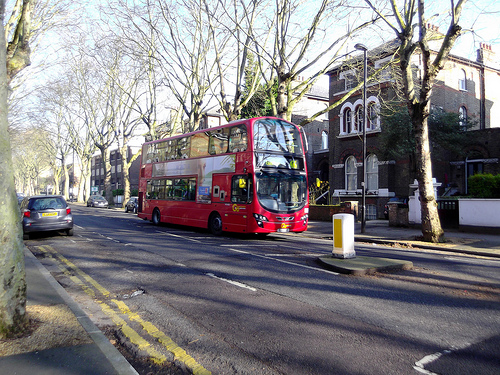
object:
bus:
[136, 115, 310, 236]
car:
[21, 194, 75, 239]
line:
[43, 244, 213, 374]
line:
[205, 270, 259, 293]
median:
[330, 212, 357, 260]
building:
[323, 19, 499, 220]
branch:
[450, 0, 456, 28]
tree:
[362, 0, 477, 244]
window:
[338, 101, 353, 137]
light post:
[353, 42, 367, 236]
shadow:
[410, 63, 495, 129]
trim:
[331, 158, 395, 170]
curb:
[355, 235, 500, 259]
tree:
[196, 0, 398, 128]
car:
[123, 195, 138, 214]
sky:
[1, 0, 500, 179]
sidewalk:
[353, 219, 499, 258]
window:
[251, 118, 304, 156]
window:
[254, 166, 308, 212]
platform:
[316, 251, 413, 276]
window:
[143, 176, 197, 201]